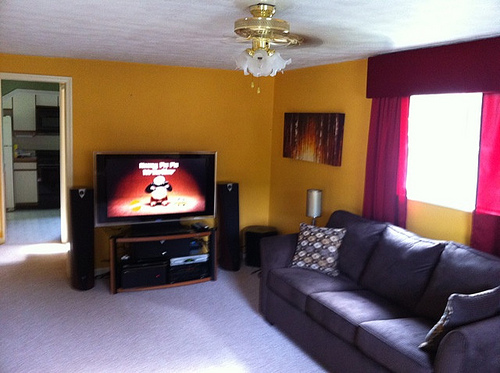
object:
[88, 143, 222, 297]
tv stand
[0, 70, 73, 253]
doorway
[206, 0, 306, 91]
fan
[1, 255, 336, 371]
carpet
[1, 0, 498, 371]
living room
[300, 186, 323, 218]
silver lamp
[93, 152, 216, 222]
flat screen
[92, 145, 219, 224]
tv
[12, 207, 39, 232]
floor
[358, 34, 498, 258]
curtains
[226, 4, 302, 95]
ceiling fan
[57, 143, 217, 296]
speaker tv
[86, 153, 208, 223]
screen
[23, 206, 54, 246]
tiled floor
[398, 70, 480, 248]
window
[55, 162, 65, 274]
framed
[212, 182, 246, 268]
speaker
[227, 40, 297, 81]
globe